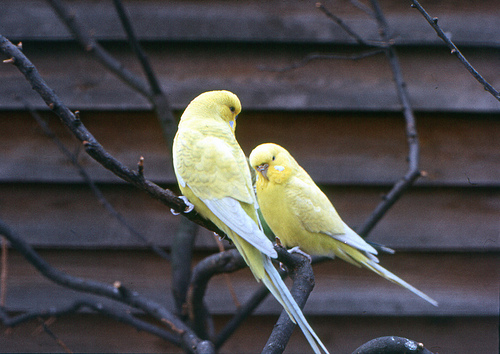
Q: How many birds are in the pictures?
A: Two.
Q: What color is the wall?
A: Brown.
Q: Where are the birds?
A: On a branch.